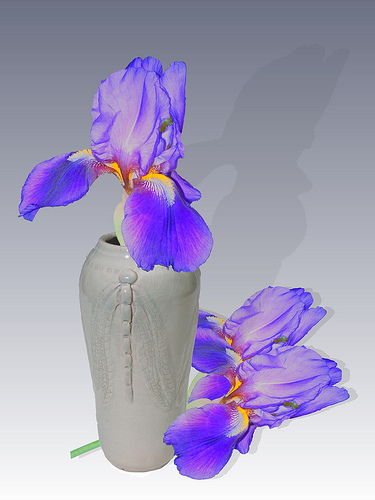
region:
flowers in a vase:
[18, 55, 246, 462]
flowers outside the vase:
[187, 285, 337, 470]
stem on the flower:
[75, 429, 102, 462]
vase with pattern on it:
[73, 231, 202, 471]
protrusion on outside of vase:
[107, 263, 148, 407]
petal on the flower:
[120, 189, 219, 269]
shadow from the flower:
[181, 40, 337, 304]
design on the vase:
[131, 295, 181, 407]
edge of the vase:
[88, 224, 133, 252]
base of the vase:
[99, 439, 172, 477]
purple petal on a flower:
[135, 190, 201, 273]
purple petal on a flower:
[25, 153, 93, 215]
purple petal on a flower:
[101, 72, 159, 145]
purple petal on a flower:
[180, 408, 222, 466]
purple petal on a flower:
[199, 321, 246, 377]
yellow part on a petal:
[139, 169, 172, 195]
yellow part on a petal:
[100, 163, 125, 185]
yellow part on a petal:
[235, 401, 253, 435]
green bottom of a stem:
[66, 438, 96, 465]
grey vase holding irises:
[75, 219, 206, 498]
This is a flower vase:
[11, 41, 219, 479]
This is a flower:
[161, 397, 253, 489]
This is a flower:
[251, 354, 326, 441]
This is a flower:
[230, 276, 320, 346]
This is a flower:
[127, 164, 202, 280]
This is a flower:
[17, 145, 102, 230]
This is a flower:
[95, 57, 164, 178]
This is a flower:
[155, 47, 221, 183]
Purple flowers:
[17, 55, 214, 276]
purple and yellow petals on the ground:
[165, 280, 350, 478]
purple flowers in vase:
[16, 56, 212, 469]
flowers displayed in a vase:
[15, 46, 212, 467]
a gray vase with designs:
[75, 229, 199, 471]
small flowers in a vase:
[16, 61, 211, 466]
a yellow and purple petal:
[121, 172, 211, 273]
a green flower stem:
[70, 438, 110, 460]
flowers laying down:
[167, 283, 354, 480]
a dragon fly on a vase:
[65, 232, 201, 475]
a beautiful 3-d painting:
[10, 40, 325, 398]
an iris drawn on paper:
[188, 323, 348, 492]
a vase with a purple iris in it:
[15, 56, 225, 402]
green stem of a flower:
[60, 435, 102, 459]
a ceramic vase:
[80, 229, 207, 474]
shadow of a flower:
[212, 48, 308, 284]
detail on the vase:
[85, 259, 177, 424]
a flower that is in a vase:
[13, 41, 186, 314]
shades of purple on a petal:
[183, 423, 221, 461]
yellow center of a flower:
[145, 171, 170, 189]